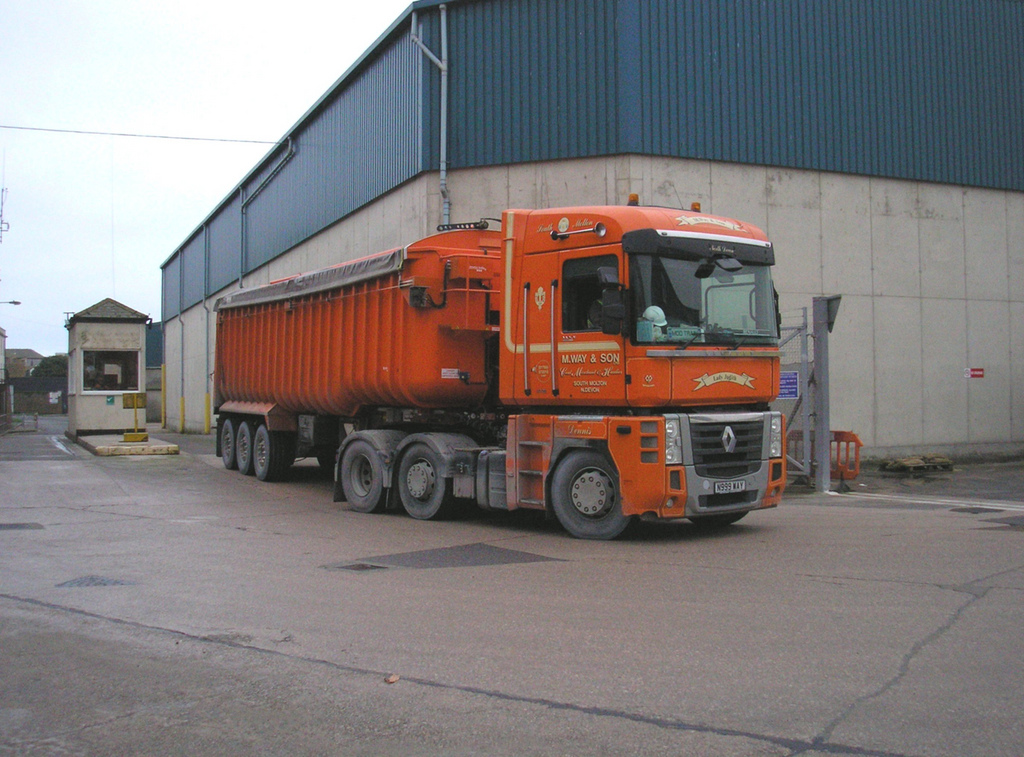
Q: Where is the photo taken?
A: Outside building.